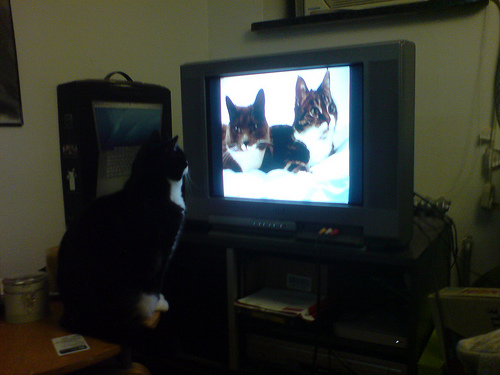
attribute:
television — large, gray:
[181, 37, 416, 249]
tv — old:
[168, 44, 440, 227]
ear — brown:
[254, 87, 266, 108]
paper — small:
[50, 331, 92, 356]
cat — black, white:
[50, 122, 192, 350]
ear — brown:
[293, 74, 306, 96]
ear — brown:
[316, 67, 331, 89]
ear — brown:
[223, 95, 236, 119]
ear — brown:
[164, 131, 179, 153]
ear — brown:
[167, 132, 181, 147]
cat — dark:
[38, 134, 191, 366]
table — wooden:
[30, 335, 57, 368]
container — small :
[2, 270, 56, 328]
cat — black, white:
[32, 117, 210, 353]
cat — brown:
[221, 84, 276, 172]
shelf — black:
[250, 1, 490, 36]